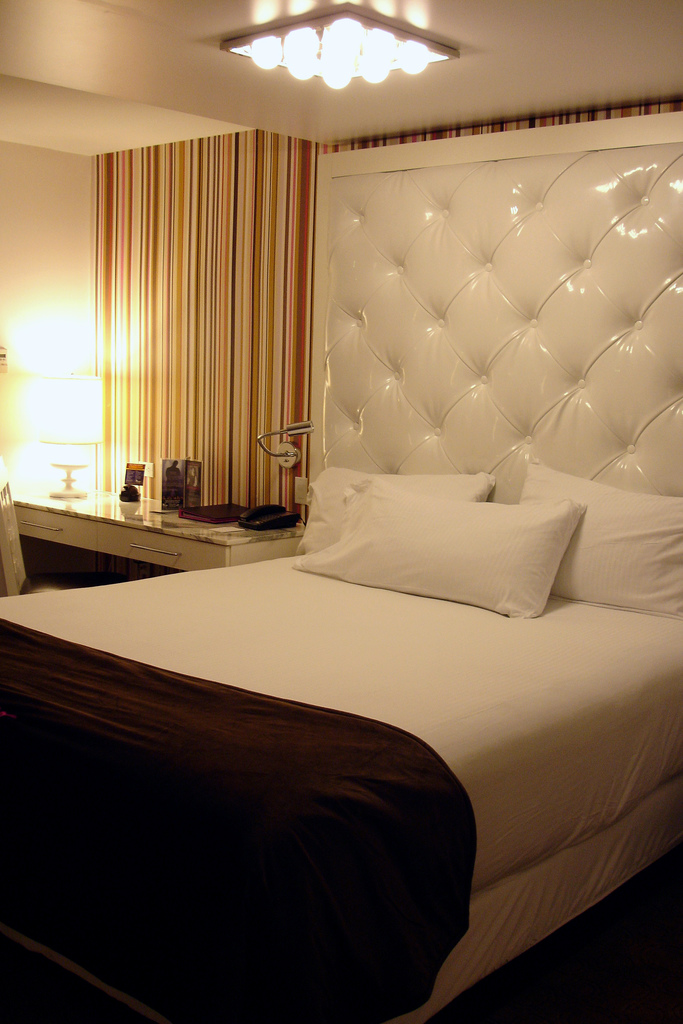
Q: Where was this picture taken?
A: The bedroom.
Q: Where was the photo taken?
A: In a bedroom.